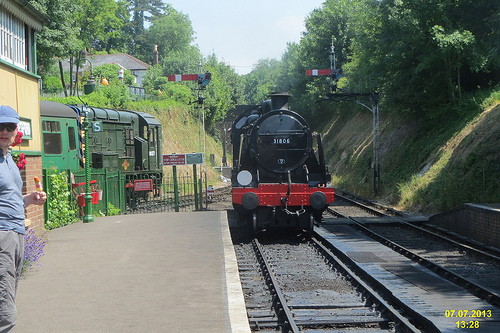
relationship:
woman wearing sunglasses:
[1, 104, 26, 333] [0, 121, 19, 137]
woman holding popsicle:
[1, 104, 26, 333] [29, 177, 50, 196]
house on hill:
[82, 50, 158, 101] [52, 96, 225, 184]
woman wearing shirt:
[1, 104, 26, 333] [2, 154, 25, 235]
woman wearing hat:
[1, 104, 26, 333] [0, 101, 20, 131]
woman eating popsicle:
[1, 104, 26, 333] [29, 177, 50, 196]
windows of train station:
[1, 6, 35, 72] [0, 0, 47, 249]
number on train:
[271, 137, 300, 146] [223, 91, 335, 245]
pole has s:
[76, 115, 95, 224] [93, 117, 107, 135]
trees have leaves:
[38, 4, 230, 108] [34, 3, 129, 60]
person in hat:
[1, 100, 27, 327] [0, 101, 20, 131]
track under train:
[249, 214, 440, 333] [223, 91, 335, 245]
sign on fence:
[132, 176, 158, 192] [45, 167, 212, 216]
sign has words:
[132, 176, 158, 192] [136, 183, 147, 188]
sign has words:
[156, 151, 193, 169] [161, 155, 187, 167]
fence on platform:
[45, 167, 212, 216] [24, 209, 252, 332]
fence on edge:
[45, 167, 212, 216] [48, 207, 229, 219]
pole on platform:
[76, 115, 95, 224] [24, 209, 252, 332]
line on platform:
[220, 209, 254, 333] [24, 209, 252, 332]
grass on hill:
[321, 104, 496, 212] [315, 72, 499, 220]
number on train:
[271, 137, 293, 145] [223, 91, 335, 245]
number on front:
[271, 137, 293, 145] [256, 112, 326, 232]